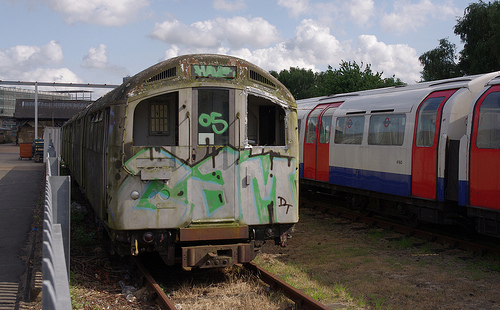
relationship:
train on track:
[54, 46, 310, 276] [139, 257, 354, 306]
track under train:
[109, 251, 344, 308] [30, 47, 341, 283]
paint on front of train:
[120, 147, 300, 228] [295, 70, 498, 211]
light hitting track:
[122, 186, 145, 203] [132, 254, 337, 309]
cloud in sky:
[20, 36, 62, 66] [4, 2, 479, 77]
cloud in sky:
[158, 15, 278, 50] [4, 2, 479, 77]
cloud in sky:
[356, 30, 428, 82] [4, 2, 479, 77]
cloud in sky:
[82, 37, 110, 72] [4, 2, 479, 77]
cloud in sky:
[290, 14, 345, 63] [4, 2, 479, 77]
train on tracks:
[54, 52, 302, 276] [102, 227, 305, 308]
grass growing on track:
[222, 271, 264, 303] [136, 259, 321, 307]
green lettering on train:
[197, 110, 227, 136] [54, 46, 310, 276]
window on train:
[366, 112, 406, 147] [297, 67, 498, 239]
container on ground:
[18, 140, 35, 160] [1, 148, 48, 288]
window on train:
[147, 97, 172, 136] [61, 53, 298, 273]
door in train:
[410, 87, 440, 189] [291, 82, 413, 189]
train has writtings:
[54, 46, 310, 276] [126, 61, 295, 221]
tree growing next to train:
[270, 59, 409, 100] [295, 70, 498, 211]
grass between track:
[278, 235, 365, 300] [109, 251, 344, 308]